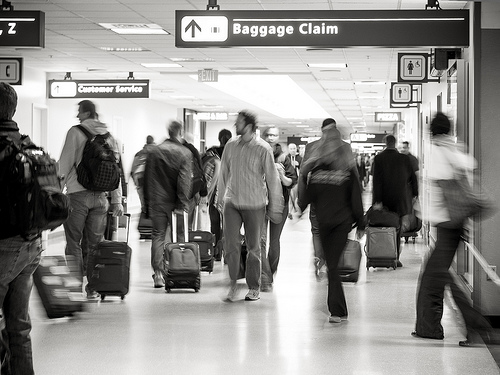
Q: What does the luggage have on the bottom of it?
A: Wheels.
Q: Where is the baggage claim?
A: Straight ahead.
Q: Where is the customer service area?
A: Forward.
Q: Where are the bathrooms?
A: On the right along the wall.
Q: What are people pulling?
A: Bags.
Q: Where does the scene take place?
A: At an airport.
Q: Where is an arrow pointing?
A: Up.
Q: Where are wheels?
A: Under the bags.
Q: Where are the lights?
A: On ceiling.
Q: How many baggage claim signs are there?
A: 1.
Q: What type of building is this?
A: Airport.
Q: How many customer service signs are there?
A: 1.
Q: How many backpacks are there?
A: 2.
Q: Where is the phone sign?
A: On the upper left corner.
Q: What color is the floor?
A: White.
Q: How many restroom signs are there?
A: 2.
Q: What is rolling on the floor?
A: Luggage.